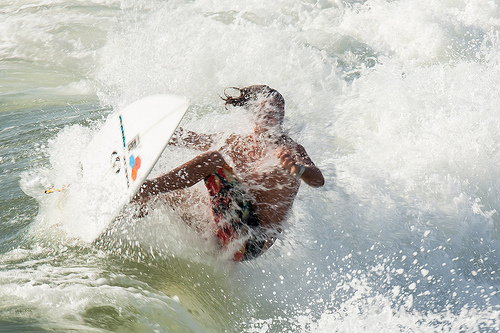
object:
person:
[128, 84, 328, 263]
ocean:
[0, 0, 500, 333]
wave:
[43, 241, 286, 326]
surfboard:
[47, 90, 193, 250]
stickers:
[107, 106, 148, 191]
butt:
[214, 230, 284, 262]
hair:
[241, 84, 285, 107]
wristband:
[296, 162, 306, 178]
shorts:
[201, 160, 271, 263]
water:
[113, 0, 500, 231]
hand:
[276, 148, 303, 175]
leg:
[131, 149, 260, 263]